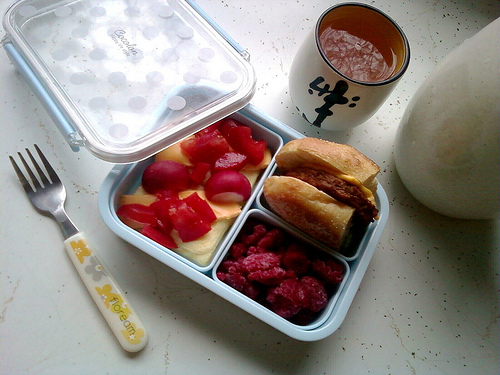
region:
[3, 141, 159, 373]
Fork on a table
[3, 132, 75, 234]
part of fork that is silver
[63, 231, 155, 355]
part o fork that is plastic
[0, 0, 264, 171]
top of container is plastic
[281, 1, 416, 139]
cup is white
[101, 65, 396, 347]
container has a meal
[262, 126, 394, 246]
sandwich is a container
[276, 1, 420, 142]
cup with chocolate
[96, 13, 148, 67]
lid has black letters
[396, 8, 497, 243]
jar of milk on right side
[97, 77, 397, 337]
meal in a container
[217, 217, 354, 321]
strawberries on a container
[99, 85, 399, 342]
container if blue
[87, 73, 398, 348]
container has 3 sections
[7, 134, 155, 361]
fork on side of container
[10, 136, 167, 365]
fork is silver and plastic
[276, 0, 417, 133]
cup with a drink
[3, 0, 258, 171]
lid of container is white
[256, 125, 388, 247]
sandwich on container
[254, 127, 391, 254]
bread is cutted in two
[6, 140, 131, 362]
fork has white handle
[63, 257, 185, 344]
handle has yellow and gray flowers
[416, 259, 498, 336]
table is white with dark specks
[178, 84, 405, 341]
food container has 3 compartments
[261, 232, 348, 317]
red raspberries are in one compartment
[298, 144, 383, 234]
part of a sandwich is in a compartment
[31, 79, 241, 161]
part of lid for food container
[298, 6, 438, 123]
white mug with black asian character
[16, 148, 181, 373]
fork is left of food container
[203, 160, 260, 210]
radish in compartment of food container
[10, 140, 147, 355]
the little fork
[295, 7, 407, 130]
the black and white cup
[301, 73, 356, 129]
oriental writing on the cup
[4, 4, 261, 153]
cover of the bento box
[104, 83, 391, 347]
bottom of the bento box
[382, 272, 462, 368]
top of the table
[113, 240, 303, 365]
shadow from the bento box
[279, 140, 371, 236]
half sandwich of the bento box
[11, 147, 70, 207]
prongs on the fork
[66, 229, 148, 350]
handle of the fork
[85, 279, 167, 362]
black letters on fork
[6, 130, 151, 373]
fork next to food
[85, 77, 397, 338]
tray of food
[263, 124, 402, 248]
sandwich of meat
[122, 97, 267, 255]
vegetables on a tray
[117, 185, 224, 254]
cutted red peppers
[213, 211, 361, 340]
berries next to sandwich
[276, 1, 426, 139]
cup of drink next to tray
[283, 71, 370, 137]
black chinese letters on cup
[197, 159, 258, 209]
half of a radish